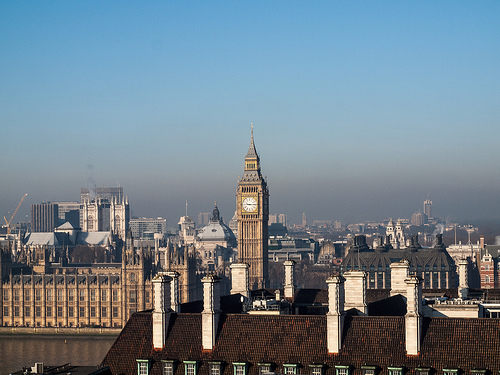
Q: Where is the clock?
A: Middle tower.